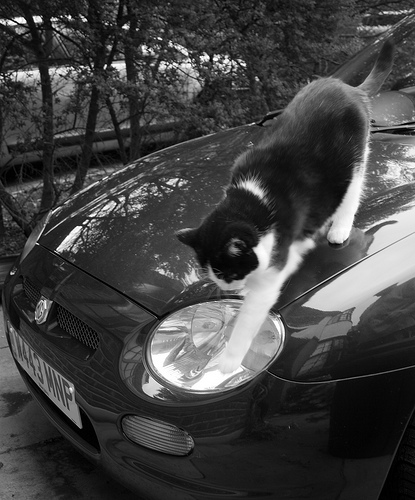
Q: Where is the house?
A: Reflected on car.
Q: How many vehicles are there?
A: 2.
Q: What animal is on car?
A: Cat.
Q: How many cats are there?
A: 1.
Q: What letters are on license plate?
A: MNP.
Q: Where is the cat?
A: On top of car.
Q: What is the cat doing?
A: Touching light.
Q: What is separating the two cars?
A: Trees.